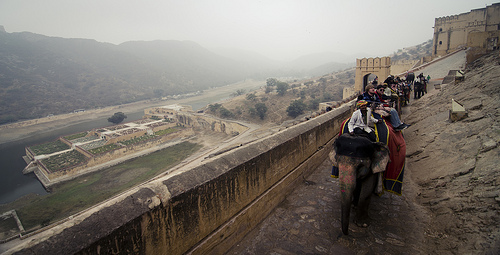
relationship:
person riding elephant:
[345, 93, 381, 151] [310, 124, 402, 244]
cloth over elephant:
[373, 114, 418, 199] [327, 116, 417, 241]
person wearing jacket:
[345, 100, 381, 144] [347, 108, 378, 135]